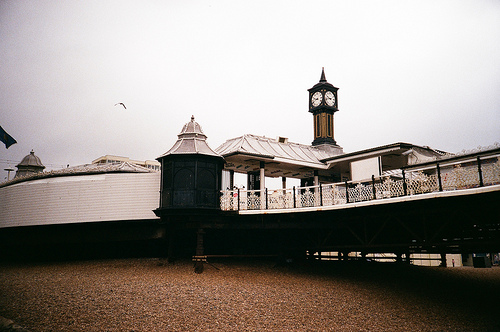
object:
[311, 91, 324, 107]
clock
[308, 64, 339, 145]
tower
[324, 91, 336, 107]
clock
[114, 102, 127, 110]
bird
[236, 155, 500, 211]
fence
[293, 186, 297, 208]
post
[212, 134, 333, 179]
roof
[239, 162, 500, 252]
bridge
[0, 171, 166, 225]
wall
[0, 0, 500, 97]
sky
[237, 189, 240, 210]
pole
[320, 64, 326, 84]
tip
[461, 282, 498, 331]
shadow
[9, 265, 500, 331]
ground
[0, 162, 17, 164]
powerlines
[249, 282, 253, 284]
gravel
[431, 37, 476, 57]
clouds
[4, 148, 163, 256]
pavillion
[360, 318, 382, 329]
sand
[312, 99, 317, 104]
hands